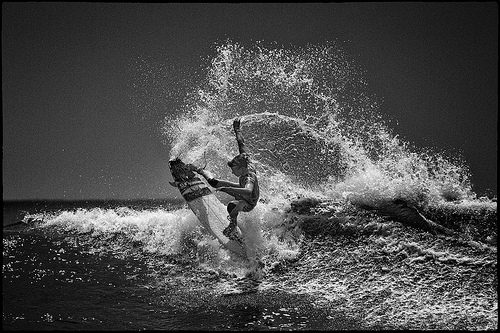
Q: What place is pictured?
A: It is an ocean.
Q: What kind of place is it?
A: It is an ocean.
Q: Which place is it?
A: It is an ocean.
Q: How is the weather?
A: It is clear.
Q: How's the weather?
A: It is clear.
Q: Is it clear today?
A: Yes, it is clear.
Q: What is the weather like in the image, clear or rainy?
A: It is clear.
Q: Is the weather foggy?
A: No, it is clear.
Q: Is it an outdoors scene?
A: Yes, it is outdoors.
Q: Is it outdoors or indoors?
A: It is outdoors.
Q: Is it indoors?
A: No, it is outdoors.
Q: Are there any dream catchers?
A: No, there are no dream catchers.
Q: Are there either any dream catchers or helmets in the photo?
A: No, there are no dream catchers or helmets.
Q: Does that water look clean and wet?
A: Yes, the water is clean and wet.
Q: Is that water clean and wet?
A: Yes, the water is clean and wet.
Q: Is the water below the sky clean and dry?
A: No, the water is clean but wet.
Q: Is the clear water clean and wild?
A: Yes, the water is clean and wild.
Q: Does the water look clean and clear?
A: Yes, the water is clean and clear.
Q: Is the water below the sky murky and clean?
A: No, the water is clean but clear.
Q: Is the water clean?
A: Yes, the water is clean.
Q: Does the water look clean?
A: Yes, the water is clean.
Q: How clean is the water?
A: The water is clean.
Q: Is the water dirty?
A: No, the water is clean.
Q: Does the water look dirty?
A: No, the water is clean.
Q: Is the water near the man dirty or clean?
A: The water is clean.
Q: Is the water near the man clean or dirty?
A: The water is clean.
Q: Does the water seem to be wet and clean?
A: Yes, the water is wet and clean.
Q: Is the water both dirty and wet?
A: No, the water is wet but clean.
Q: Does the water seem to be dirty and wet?
A: No, the water is wet but clean.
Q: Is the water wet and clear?
A: Yes, the water is wet and clear.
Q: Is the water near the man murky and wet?
A: No, the water is wet but clear.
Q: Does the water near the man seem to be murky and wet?
A: No, the water is wet but clear.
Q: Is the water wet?
A: Yes, the water is wet.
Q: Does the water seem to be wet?
A: Yes, the water is wet.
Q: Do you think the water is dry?
A: No, the water is wet.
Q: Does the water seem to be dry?
A: No, the water is wet.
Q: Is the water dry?
A: No, the water is wet.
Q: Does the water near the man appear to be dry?
A: No, the water is wet.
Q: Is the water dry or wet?
A: The water is wet.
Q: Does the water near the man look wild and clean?
A: Yes, the water is wild and clean.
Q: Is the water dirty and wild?
A: No, the water is wild but clean.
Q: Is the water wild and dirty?
A: No, the water is wild but clean.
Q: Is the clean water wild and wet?
A: Yes, the water is wild and wet.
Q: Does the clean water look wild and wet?
A: Yes, the water is wild and wet.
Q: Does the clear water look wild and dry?
A: No, the water is wild but wet.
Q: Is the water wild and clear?
A: Yes, the water is wild and clear.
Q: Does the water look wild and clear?
A: Yes, the water is wild and clear.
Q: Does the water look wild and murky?
A: No, the water is wild but clear.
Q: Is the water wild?
A: Yes, the water is wild.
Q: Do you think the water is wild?
A: Yes, the water is wild.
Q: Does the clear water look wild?
A: Yes, the water is wild.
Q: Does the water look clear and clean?
A: Yes, the water is clear and clean.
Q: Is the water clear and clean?
A: Yes, the water is clear and clean.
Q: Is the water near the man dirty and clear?
A: No, the water is clear but clean.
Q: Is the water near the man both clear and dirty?
A: No, the water is clear but clean.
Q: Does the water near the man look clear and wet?
A: Yes, the water is clear and wet.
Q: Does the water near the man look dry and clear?
A: No, the water is clear but wet.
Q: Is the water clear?
A: Yes, the water is clear.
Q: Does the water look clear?
A: Yes, the water is clear.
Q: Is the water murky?
A: No, the water is clear.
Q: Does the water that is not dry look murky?
A: No, the water is clear.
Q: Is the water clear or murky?
A: The water is clear.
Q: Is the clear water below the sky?
A: Yes, the water is below the sky.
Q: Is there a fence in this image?
A: No, there are no fences.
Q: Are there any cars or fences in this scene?
A: No, there are no fences or cars.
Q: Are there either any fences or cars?
A: No, there are no fences or cars.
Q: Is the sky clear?
A: Yes, the sky is clear.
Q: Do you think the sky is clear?
A: Yes, the sky is clear.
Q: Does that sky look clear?
A: Yes, the sky is clear.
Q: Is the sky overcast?
A: No, the sky is clear.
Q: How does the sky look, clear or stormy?
A: The sky is clear.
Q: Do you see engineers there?
A: No, there are no engineers.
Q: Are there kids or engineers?
A: No, there are no engineers or kids.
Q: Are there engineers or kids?
A: No, there are no engineers or kids.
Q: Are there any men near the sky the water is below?
A: Yes, there is a man near the sky.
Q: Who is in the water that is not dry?
A: The man is in the water.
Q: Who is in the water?
A: The man is in the water.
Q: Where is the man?
A: The man is in the water.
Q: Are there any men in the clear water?
A: Yes, there is a man in the water.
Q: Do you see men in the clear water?
A: Yes, there is a man in the water.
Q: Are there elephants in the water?
A: No, there is a man in the water.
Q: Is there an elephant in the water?
A: No, there is a man in the water.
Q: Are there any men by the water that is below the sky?
A: Yes, there is a man by the water.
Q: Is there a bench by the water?
A: No, there is a man by the water.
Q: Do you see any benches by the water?
A: No, there is a man by the water.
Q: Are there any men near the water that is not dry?
A: Yes, there is a man near the water.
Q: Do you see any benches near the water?
A: No, there is a man near the water.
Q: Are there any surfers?
A: Yes, there is a surfer.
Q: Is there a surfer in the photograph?
A: Yes, there is a surfer.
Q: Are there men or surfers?
A: Yes, there is a surfer.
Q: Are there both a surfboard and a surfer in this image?
A: Yes, there are both a surfer and a surfboard.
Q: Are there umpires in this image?
A: No, there are no umpires.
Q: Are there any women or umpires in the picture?
A: No, there are no umpires or women.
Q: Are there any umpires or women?
A: No, there are no umpires or women.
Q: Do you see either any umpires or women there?
A: No, there are no umpires or women.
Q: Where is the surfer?
A: The surfer is in the ocean.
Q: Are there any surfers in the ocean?
A: Yes, there is a surfer in the ocean.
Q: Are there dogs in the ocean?
A: No, there is a surfer in the ocean.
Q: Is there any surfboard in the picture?
A: Yes, there is a surfboard.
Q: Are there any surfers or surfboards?
A: Yes, there is a surfboard.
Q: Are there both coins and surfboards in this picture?
A: No, there is a surfboard but no coins.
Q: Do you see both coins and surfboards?
A: No, there is a surfboard but no coins.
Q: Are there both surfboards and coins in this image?
A: No, there is a surfboard but no coins.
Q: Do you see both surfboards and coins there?
A: No, there is a surfboard but no coins.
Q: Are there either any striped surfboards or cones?
A: Yes, there is a striped surfboard.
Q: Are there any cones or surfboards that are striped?
A: Yes, the surfboard is striped.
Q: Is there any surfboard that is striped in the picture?
A: Yes, there is a striped surfboard.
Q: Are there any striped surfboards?
A: Yes, there is a striped surfboard.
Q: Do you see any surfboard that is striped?
A: Yes, there is a surfboard that is striped.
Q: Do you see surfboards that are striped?
A: Yes, there is a surfboard that is striped.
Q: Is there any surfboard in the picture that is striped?
A: Yes, there is a surfboard that is striped.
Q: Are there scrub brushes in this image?
A: No, there are no scrub brushes.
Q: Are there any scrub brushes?
A: No, there are no scrub brushes.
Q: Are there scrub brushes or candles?
A: No, there are no scrub brushes or candles.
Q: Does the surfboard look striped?
A: Yes, the surfboard is striped.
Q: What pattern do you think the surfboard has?
A: The surfboard has striped pattern.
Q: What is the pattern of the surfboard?
A: The surfboard is striped.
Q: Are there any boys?
A: No, there are no boys.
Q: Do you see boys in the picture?
A: No, there are no boys.